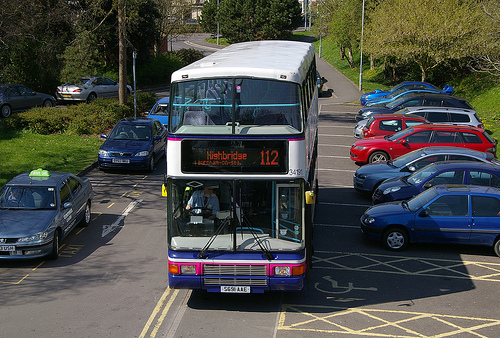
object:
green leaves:
[209, 0, 304, 42]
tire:
[381, 228, 410, 251]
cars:
[360, 113, 456, 137]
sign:
[179, 135, 290, 175]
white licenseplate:
[1, 245, 14, 252]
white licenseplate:
[112, 156, 130, 163]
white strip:
[168, 248, 308, 265]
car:
[371, 159, 499, 206]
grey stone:
[160, 40, 317, 295]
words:
[191, 147, 250, 171]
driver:
[185, 179, 220, 216]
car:
[352, 145, 499, 196]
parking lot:
[0, 69, 500, 338]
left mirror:
[305, 190, 316, 204]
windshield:
[167, 178, 306, 260]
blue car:
[358, 184, 500, 258]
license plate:
[220, 286, 251, 294]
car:
[0, 84, 60, 117]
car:
[56, 75, 133, 103]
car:
[97, 117, 168, 172]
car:
[0, 167, 94, 260]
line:
[148, 306, 170, 335]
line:
[139, 298, 167, 336]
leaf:
[217, 11, 225, 18]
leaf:
[247, 4, 254, 10]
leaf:
[234, 16, 244, 23]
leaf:
[276, 9, 281, 18]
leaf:
[210, 3, 216, 12]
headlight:
[180, 264, 197, 274]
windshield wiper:
[196, 201, 273, 260]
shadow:
[187, 184, 473, 318]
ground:
[0, 36, 496, 337]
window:
[417, 193, 468, 216]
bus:
[162, 40, 320, 294]